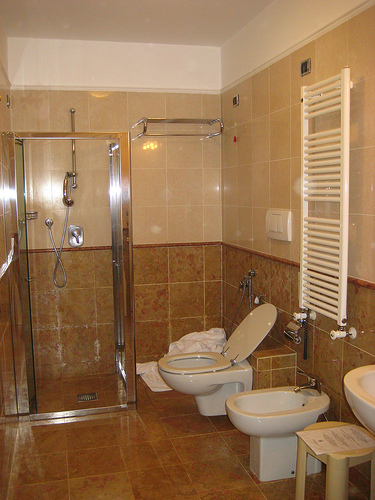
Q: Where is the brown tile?
A: On the floor.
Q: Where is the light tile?
A: On the wall.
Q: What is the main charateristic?
A: A beige color in the bathroom.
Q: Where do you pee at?
A: The toilet.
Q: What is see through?
A: A clear shower stall.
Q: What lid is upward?
A: The lid of a toilet is up.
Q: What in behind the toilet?
A: A window in front a toilet.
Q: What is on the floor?
A: A sink on the floor.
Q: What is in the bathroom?
A: A shower in a bathroom.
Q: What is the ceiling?
A: White.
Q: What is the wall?
A: Tile.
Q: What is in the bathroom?
A: A white porcelain bidet is in the bathroom.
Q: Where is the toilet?
A: Attached to the wall.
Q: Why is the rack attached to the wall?
A: To warm towels.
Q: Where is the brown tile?
A: On the floor and lower walls.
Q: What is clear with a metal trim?
A: A shower door.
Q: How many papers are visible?
A: One.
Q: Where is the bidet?
A: To the left of the stool with the paper on it.